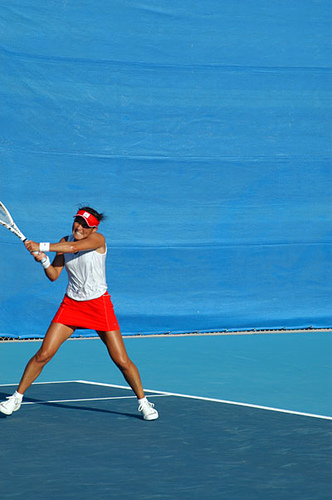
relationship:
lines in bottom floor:
[70, 377, 329, 426] [1, 378, 332, 499]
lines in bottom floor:
[0, 377, 80, 390] [1, 378, 332, 499]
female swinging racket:
[0, 205, 158, 422] [0, 199, 38, 256]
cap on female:
[72, 209, 99, 227] [0, 205, 158, 422]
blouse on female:
[64, 234, 107, 301] [0, 205, 158, 422]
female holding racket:
[0, 205, 158, 422] [0, 199, 45, 265]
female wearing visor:
[0, 205, 158, 422] [69, 203, 99, 228]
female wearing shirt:
[0, 205, 158, 422] [58, 236, 112, 308]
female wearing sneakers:
[0, 205, 158, 422] [1, 390, 162, 422]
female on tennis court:
[0, 205, 158, 422] [3, 330, 330, 498]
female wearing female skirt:
[0, 205, 158, 422] [49, 288, 119, 335]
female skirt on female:
[49, 288, 119, 335] [0, 205, 158, 422]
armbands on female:
[35, 238, 55, 269] [0, 205, 158, 422]